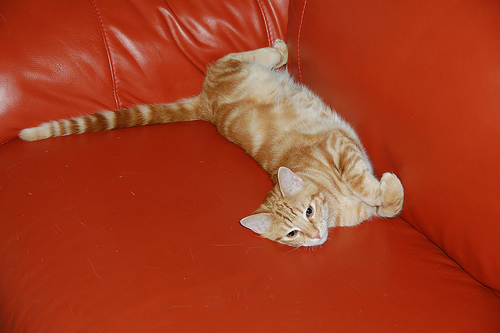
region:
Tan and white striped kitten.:
[18, 37, 403, 247]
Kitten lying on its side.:
[18, 40, 403, 247]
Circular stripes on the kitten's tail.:
[13, 87, 210, 143]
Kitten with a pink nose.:
[308, 227, 321, 241]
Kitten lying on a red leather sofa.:
[0, 6, 499, 332]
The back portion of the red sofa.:
[290, 0, 499, 290]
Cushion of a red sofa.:
[1, 121, 499, 332]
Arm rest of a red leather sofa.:
[0, 0, 287, 138]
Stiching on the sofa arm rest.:
[92, 3, 120, 112]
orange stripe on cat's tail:
[48, 121, 54, 138]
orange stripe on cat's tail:
[55, 116, 67, 136]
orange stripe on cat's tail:
[64, 119, 79, 135]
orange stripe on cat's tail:
[82, 115, 94, 130]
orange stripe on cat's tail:
[91, 112, 107, 128]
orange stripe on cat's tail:
[111, 109, 120, 129]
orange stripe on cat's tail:
[123, 108, 130, 128]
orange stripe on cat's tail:
[144, 104, 161, 124]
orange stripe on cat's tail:
[161, 105, 171, 122]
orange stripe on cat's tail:
[175, 100, 187, 120]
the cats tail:
[19, 124, 69, 143]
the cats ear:
[236, 207, 266, 232]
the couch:
[86, 165, 206, 302]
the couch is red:
[134, 196, 210, 271]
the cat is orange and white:
[239, 94, 307, 145]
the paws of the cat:
[371, 175, 406, 217]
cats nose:
[309, 224, 319, 237]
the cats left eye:
[304, 206, 324, 220]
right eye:
[280, 228, 298, 241]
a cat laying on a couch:
[0, 23, 482, 302]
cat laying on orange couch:
[8, 22, 497, 307]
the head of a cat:
[236, 164, 345, 271]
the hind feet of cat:
[193, 33, 303, 83]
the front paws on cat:
[349, 160, 406, 224]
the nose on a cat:
[307, 224, 324, 241]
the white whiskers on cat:
[290, 239, 310, 263]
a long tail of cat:
[0, 72, 227, 212]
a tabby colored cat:
[5, 29, 437, 263]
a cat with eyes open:
[269, 191, 323, 242]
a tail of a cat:
[14, 94, 207, 144]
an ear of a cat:
[274, 161, 307, 203]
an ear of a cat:
[234, 203, 274, 234]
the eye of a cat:
[280, 223, 301, 244]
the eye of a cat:
[301, 197, 318, 224]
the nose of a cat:
[301, 220, 323, 243]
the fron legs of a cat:
[336, 125, 406, 226]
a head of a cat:
[240, 156, 330, 251]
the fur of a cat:
[235, 92, 288, 135]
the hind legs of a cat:
[203, 34, 294, 96]